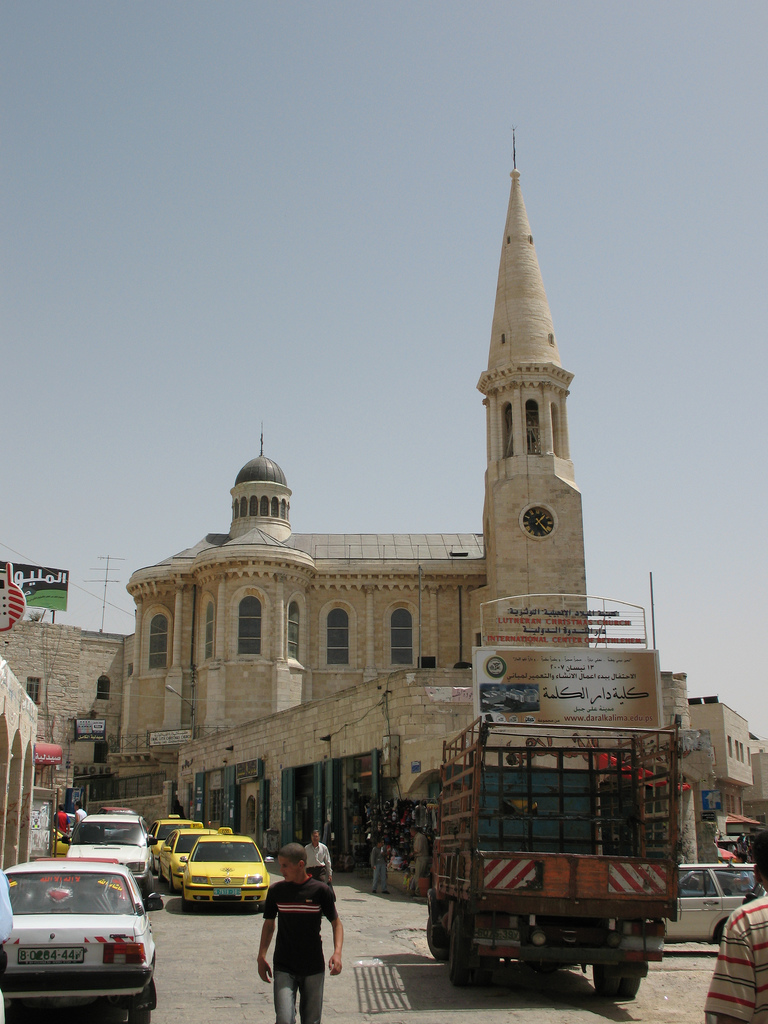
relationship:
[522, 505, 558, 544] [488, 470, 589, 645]
clock built into stone wall